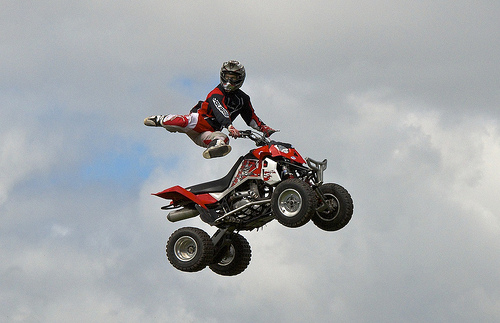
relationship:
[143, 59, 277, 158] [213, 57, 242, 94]
man wearing helmet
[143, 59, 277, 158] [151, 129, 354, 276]
man on atv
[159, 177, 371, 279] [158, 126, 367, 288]
wheels on atv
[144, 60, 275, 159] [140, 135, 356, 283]
man on 4 wheeler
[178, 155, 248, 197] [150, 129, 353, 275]
black seat on 4 wheeler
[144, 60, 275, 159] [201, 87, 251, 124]
man wearing top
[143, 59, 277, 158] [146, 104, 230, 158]
man wearing pants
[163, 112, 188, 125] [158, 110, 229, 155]
trim on pants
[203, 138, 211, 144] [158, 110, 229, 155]
trim on pants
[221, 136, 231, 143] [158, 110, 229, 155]
trim on pants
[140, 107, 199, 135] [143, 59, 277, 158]
leg of man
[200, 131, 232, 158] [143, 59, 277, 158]
leg of man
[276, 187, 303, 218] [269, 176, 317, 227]
rim on tire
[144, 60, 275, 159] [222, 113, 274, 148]
man holding bars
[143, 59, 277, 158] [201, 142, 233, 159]
man wearing boot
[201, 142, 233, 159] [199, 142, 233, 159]
boot on foot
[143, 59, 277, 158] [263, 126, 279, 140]
man holding on handle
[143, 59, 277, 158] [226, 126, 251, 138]
man holding on handle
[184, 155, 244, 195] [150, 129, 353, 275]
black seat of 4 wheeler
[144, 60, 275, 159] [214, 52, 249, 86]
man wearing helmet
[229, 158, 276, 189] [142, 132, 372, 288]
decal on bike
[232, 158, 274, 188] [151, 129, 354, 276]
decal on atv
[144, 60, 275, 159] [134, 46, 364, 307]
man doing a trick